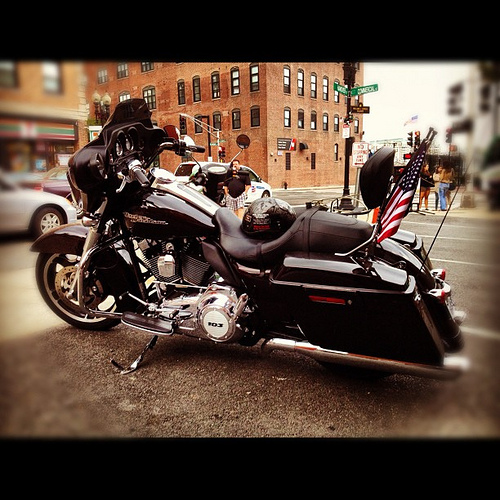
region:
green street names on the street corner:
[328, 83, 378, 95]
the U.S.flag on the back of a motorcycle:
[381, 125, 435, 247]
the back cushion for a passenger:
[356, 139, 393, 209]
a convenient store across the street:
[1, 118, 79, 138]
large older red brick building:
[123, 60, 357, 187]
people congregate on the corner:
[423, 161, 453, 213]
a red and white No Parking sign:
[350, 139, 370, 171]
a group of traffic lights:
[406, 66, 492, 156]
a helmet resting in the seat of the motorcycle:
[241, 191, 291, 241]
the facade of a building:
[264, 60, 360, 192]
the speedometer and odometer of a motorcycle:
[107, 128, 138, 158]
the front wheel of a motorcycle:
[23, 215, 128, 335]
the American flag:
[369, 124, 433, 250]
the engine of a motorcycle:
[128, 236, 212, 298]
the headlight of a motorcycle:
[56, 141, 91, 196]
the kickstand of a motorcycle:
[99, 333, 181, 382]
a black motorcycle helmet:
[239, 195, 296, 238]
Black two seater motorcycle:
[37, 91, 472, 380]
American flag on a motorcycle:
[373, 128, 440, 249]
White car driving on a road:
[0, 171, 77, 238]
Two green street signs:
[331, 80, 380, 98]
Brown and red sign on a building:
[273, 135, 298, 152]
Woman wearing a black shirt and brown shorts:
[417, 162, 435, 211]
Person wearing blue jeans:
[437, 156, 453, 211]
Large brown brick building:
[80, 59, 367, 189]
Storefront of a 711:
[0, 113, 77, 178]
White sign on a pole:
[350, 138, 371, 209]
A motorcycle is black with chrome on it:
[30, 98, 470, 380]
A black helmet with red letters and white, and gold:
[242, 198, 292, 237]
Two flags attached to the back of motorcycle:
[375, 125, 437, 244]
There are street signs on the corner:
[331, 80, 379, 165]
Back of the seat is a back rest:
[333, 143, 397, 258]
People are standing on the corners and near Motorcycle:
[223, 158, 493, 220]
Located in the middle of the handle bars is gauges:
[68, 127, 162, 177]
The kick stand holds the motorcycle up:
[107, 335, 158, 373]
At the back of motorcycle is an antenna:
[422, 154, 472, 265]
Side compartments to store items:
[271, 229, 441, 382]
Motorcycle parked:
[32, 100, 474, 408]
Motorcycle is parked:
[29, 92, 474, 396]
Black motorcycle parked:
[28, 93, 473, 400]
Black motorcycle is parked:
[30, 95, 477, 392]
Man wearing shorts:
[224, 187, 251, 214]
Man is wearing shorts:
[219, 190, 248, 213]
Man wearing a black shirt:
[225, 168, 255, 200]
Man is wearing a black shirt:
[217, 166, 250, 197]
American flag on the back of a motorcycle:
[366, 121, 445, 258]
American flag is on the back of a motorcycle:
[359, 123, 445, 272]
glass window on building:
[283, 103, 291, 125]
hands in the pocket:
[221, 187, 248, 204]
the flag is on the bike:
[390, 132, 424, 244]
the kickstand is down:
[115, 330, 165, 392]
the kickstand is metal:
[120, 337, 167, 387]